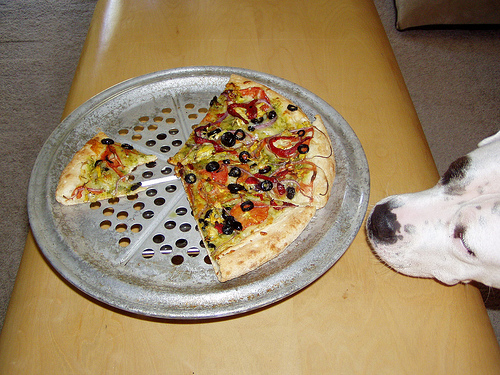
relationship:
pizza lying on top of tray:
[48, 66, 346, 296] [25, 62, 373, 320]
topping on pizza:
[227, 167, 243, 177] [48, 66, 346, 296]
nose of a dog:
[366, 201, 398, 250] [369, 120, 483, 283]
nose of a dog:
[366, 201, 398, 240] [369, 120, 483, 283]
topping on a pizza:
[227, 167, 243, 177] [175, 70, 339, 280]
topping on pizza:
[227, 167, 243, 177] [170, 66, 346, 289]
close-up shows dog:
[19, 53, 499, 343] [365, 132, 499, 288]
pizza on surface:
[48, 66, 346, 296] [13, 7, 478, 372]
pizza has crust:
[48, 66, 346, 296] [306, 124, 335, 213]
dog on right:
[357, 121, 498, 291] [417, 2, 491, 372]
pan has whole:
[13, 59, 376, 328] [117, 232, 131, 248]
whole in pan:
[142, 136, 156, 153] [13, 59, 376, 328]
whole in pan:
[142, 130, 156, 153] [13, 59, 376, 328]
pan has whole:
[13, 59, 376, 328] [130, 201, 144, 215]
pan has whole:
[13, 59, 376, 328] [161, 181, 177, 197]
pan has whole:
[13, 59, 376, 328] [141, 203, 155, 223]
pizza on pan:
[48, 66, 346, 296] [13, 59, 376, 328]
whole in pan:
[166, 119, 182, 139] [13, 59, 376, 328]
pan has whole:
[13, 59, 376, 328] [142, 184, 156, 196]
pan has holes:
[27, 65, 370, 321] [124, 195, 198, 258]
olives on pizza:
[258, 177, 275, 194] [175, 163, 322, 284]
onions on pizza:
[266, 134, 322, 194] [170, 66, 346, 289]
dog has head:
[357, 121, 498, 291] [359, 117, 499, 295]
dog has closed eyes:
[365, 132, 499, 288] [456, 225, 476, 255]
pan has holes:
[27, 65, 370, 321] [165, 240, 194, 270]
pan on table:
[27, 65, 370, 321] [314, 301, 446, 360]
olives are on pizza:
[219, 212, 243, 236] [180, 165, 312, 274]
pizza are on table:
[194, 80, 315, 262] [328, 304, 466, 365]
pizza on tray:
[177, 166, 314, 283] [105, 215, 189, 306]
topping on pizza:
[227, 167, 243, 177] [194, 79, 330, 263]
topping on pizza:
[227, 167, 243, 177] [170, 155, 308, 278]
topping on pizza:
[227, 167, 243, 177] [180, 165, 312, 274]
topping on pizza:
[212, 160, 255, 182] [204, 140, 335, 208]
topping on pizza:
[212, 127, 250, 150] [170, 66, 346, 289]